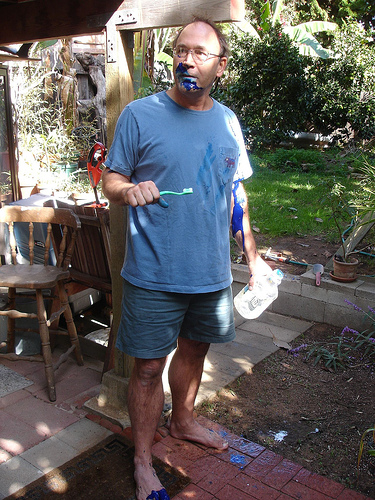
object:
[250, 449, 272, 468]
bricks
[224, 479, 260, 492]
bricks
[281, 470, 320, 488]
bricks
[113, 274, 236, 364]
shorts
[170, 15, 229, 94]
head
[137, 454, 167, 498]
barefoot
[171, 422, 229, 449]
barefoot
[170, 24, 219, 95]
face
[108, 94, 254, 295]
blue shirt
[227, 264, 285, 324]
bottle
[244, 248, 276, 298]
hand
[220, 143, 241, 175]
paint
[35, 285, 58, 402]
leg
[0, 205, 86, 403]
chair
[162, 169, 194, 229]
toothbrush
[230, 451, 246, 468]
paint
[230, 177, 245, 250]
paint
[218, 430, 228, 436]
paint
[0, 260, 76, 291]
seat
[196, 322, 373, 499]
ground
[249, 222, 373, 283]
ground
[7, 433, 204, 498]
ground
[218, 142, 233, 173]
shirt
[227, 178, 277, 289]
arm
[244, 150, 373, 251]
grass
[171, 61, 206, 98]
blue paint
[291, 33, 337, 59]
leaf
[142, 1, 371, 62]
plant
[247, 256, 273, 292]
hand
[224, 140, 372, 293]
ground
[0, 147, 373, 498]
ground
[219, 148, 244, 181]
pocket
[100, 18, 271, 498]
man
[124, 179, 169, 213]
hand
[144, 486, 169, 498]
paint